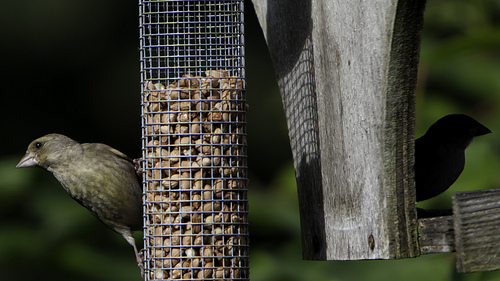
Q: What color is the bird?
A: Brown.